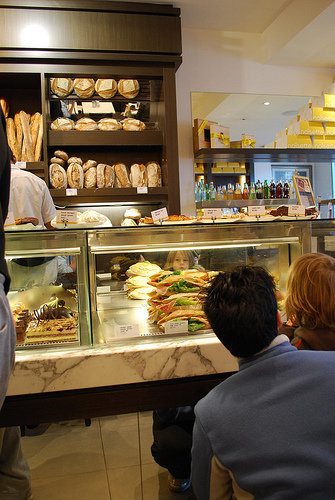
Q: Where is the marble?
A: In front of the display case.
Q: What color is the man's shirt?
A: Blue.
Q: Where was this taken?
A: Deli.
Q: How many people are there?
A: 4.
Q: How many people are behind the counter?
A: 1.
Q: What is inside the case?
A: Food.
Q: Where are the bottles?
A: On top of the case.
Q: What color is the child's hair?
A: Blonde.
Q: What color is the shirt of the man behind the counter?
A: White.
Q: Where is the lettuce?
A: On the sandwiches.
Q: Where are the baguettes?
A: On the shelf.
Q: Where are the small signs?
A: In front of the food.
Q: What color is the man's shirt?
A: Blue.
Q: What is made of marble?
A: Counter.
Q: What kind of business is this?
A: A bakery.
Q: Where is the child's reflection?
A: The glass display case.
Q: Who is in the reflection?
A: The child.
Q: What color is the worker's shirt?
A: White.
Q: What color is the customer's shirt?
A: Blue.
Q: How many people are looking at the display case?
A: Two.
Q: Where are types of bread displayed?
A: On shelves behind the counter.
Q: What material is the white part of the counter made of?
A: Marble.